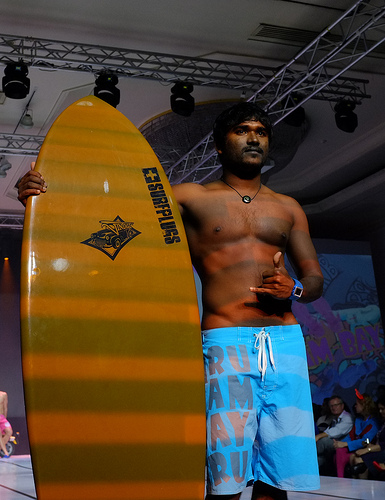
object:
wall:
[0, 191, 385, 457]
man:
[16, 104, 324, 499]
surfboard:
[18, 94, 207, 499]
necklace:
[219, 178, 262, 205]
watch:
[290, 279, 305, 302]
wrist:
[289, 276, 309, 305]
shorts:
[199, 316, 324, 499]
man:
[314, 392, 353, 469]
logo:
[78, 211, 145, 263]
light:
[333, 93, 362, 138]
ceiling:
[0, 0, 384, 260]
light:
[276, 89, 309, 132]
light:
[165, 79, 201, 119]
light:
[92, 65, 121, 110]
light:
[0, 53, 34, 99]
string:
[252, 327, 276, 384]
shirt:
[322, 411, 354, 440]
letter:
[224, 340, 252, 374]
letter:
[204, 342, 226, 378]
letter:
[225, 373, 255, 411]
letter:
[205, 374, 227, 412]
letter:
[226, 410, 252, 449]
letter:
[208, 410, 234, 453]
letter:
[228, 448, 250, 486]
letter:
[206, 447, 232, 491]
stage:
[0, 448, 383, 498]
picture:
[2, 2, 383, 498]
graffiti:
[281, 246, 384, 406]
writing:
[139, 163, 182, 245]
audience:
[330, 386, 378, 491]